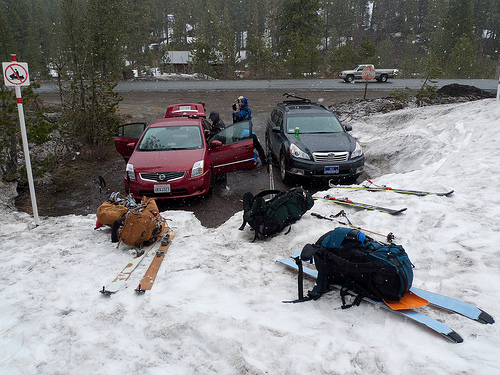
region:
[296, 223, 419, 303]
A large blue and black bag on a pair of skis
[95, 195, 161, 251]
Large yellow bag near two skis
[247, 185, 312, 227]
A green bag in front of the cars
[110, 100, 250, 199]
A large red vehicle with its doors open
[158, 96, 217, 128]
The trunk of the car is open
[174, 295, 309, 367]
Thin white snow has fallen on the ground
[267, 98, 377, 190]
A large black vehicle by the snow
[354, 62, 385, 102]
A red stop sign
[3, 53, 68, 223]
A tall white pole with a sign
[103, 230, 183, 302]
A pair of yellow and white skis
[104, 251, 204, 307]
set of skis outside of car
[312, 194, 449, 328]
backpack lying on top of skis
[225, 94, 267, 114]
person standing with camera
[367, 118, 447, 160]
dirty patch of white and grey snow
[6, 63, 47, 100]
no snow mobiling sign on pole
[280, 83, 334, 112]
ski rack on top of car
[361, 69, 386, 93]
red stop sign with snow partially covering it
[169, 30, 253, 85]
cabin in middle of picture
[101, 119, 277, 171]
red car with open side doors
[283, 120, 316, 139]
drink in green bottle with sivler top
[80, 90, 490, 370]
Two cars parked near a ski resort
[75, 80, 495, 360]
The ski equipment is on the snow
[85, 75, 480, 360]
The backpacks are on the snow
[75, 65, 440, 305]
People are getting out of a car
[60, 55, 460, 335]
People are preparing to go skiing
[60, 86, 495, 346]
People have their ski gear laid out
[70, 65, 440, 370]
Two cars parked on a road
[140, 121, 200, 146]
Windshield of a nice car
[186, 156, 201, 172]
Headlight of a new car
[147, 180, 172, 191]
License plate of a red car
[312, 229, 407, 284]
the bag is black and blue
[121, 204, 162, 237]
the bag is brown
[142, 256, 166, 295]
the ski is brown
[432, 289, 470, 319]
the ski is light blue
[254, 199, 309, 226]
the bage is black and green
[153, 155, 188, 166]
the car is red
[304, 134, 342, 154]
the car is black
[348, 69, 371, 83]
the truck is silver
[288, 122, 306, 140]
the bottle is green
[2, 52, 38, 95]
the sign is for no skimobile's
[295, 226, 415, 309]
bag on top of skis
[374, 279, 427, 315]
shovel under the bag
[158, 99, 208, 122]
trunk is open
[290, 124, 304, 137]
bottle on the hood of car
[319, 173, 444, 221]
skis in the snow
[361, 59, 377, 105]
STOP written on street sign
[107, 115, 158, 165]
car door is open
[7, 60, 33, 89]
picture of snowmobile with red line through it on street sign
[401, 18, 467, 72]
snow falling down to the ground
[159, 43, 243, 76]
house across the street